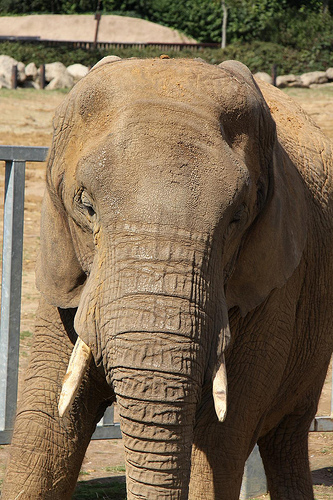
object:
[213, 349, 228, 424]
tusk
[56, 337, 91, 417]
tusk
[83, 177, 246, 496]
elephant trunk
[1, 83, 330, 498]
dirt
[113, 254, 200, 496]
trunk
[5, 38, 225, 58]
railing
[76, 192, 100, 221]
eye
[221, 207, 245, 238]
eye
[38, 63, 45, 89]
posts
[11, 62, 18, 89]
posts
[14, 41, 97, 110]
boulders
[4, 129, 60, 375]
gate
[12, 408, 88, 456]
wrinkle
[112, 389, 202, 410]
wrinkle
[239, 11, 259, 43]
trees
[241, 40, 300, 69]
bushes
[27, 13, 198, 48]
building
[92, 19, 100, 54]
pole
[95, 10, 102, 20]
transformer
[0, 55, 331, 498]
elephant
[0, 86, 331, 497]
enclosure